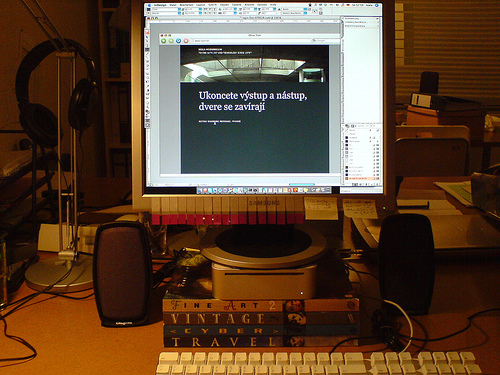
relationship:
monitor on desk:
[142, 0, 380, 196] [2, 0, 499, 375]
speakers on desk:
[377, 214, 427, 295] [2, 0, 499, 375]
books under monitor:
[161, 248, 361, 349] [124, 9, 398, 225]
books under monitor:
[160, 295, 367, 350] [124, 9, 398, 225]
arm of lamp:
[15, 5, 83, 269] [24, 2, 92, 292]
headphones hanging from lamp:
[13, 32, 105, 151] [7, 0, 96, 291]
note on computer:
[302, 191, 339, 222] [79, 12, 430, 373]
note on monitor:
[304, 195, 339, 219] [131, 0, 395, 212]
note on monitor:
[343, 199, 380, 224] [131, 0, 395, 212]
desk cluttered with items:
[2, 0, 494, 370] [45, 217, 453, 347]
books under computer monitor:
[155, 291, 361, 350] [115, 11, 407, 206]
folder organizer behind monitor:
[393, 122, 474, 179] [131, 0, 395, 212]